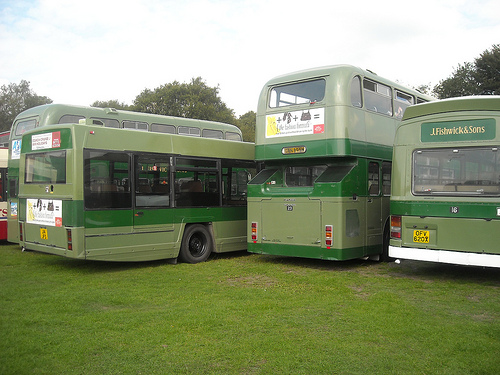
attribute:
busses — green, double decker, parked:
[244, 63, 437, 269]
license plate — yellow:
[410, 227, 430, 246]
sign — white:
[261, 107, 330, 139]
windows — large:
[363, 73, 395, 120]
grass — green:
[2, 239, 499, 372]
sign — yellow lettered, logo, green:
[418, 117, 499, 143]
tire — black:
[178, 222, 213, 265]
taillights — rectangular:
[324, 222, 332, 250]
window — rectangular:
[267, 78, 328, 112]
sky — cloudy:
[2, 2, 499, 120]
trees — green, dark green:
[427, 41, 499, 101]